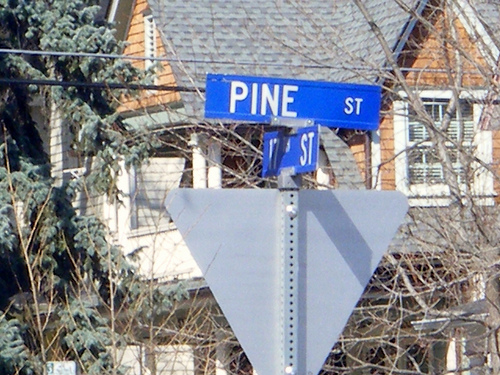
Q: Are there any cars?
A: No, there are no cars.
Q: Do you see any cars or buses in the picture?
A: No, there are no cars or buses.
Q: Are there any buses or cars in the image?
A: No, there are no cars or buses.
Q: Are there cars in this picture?
A: No, there are no cars.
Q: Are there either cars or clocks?
A: No, there are no cars or clocks.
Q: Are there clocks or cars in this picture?
A: No, there are no cars or clocks.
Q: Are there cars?
A: No, there are no cars.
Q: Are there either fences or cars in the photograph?
A: No, there are no cars or fences.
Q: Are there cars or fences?
A: No, there are no cars or fences.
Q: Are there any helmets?
A: No, there are no helmets.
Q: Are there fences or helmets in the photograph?
A: No, there are no helmets or fences.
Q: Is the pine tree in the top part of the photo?
A: Yes, the pine tree is in the top of the image.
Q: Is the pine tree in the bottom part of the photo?
A: No, the pine tree is in the top of the image.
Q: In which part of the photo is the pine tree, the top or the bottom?
A: The pine tree is in the top of the image.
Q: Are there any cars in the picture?
A: No, there are no cars.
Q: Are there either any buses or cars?
A: No, there are no cars or buses.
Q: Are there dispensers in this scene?
A: No, there are no dispensers.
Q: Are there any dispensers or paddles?
A: No, there are no dispensers or paddles.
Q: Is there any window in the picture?
A: Yes, there is a window.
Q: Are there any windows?
A: Yes, there is a window.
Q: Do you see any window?
A: Yes, there is a window.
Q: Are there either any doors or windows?
A: Yes, there is a window.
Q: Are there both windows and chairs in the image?
A: No, there is a window but no chairs.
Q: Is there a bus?
A: No, there are no buses.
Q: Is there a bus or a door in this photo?
A: No, there are no buses or doors.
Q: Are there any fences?
A: No, there are no fences.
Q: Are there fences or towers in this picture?
A: No, there are no fences or towers.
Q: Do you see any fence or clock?
A: No, there are no fences or clocks.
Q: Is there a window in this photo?
A: Yes, there is a window.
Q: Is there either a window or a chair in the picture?
A: Yes, there is a window.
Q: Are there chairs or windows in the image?
A: Yes, there is a window.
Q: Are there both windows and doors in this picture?
A: No, there is a window but no doors.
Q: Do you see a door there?
A: No, there are no doors.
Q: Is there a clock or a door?
A: No, there are no doors or clocks.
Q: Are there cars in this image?
A: No, there are no cars.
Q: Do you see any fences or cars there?
A: No, there are no cars or fences.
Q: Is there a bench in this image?
A: No, there are no benches.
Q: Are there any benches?
A: No, there are no benches.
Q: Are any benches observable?
A: No, there are no benches.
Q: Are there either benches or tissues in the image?
A: No, there are no benches or tissues.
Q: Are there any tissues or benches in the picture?
A: No, there are no benches or tissues.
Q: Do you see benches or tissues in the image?
A: No, there are no benches or tissues.